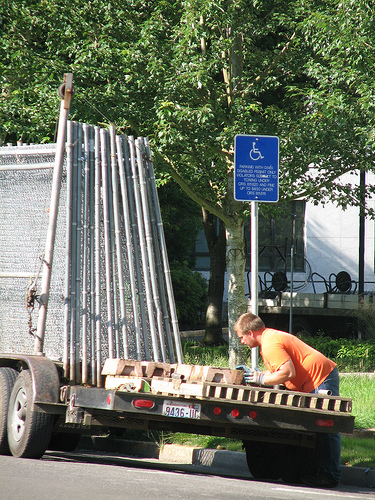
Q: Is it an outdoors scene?
A: Yes, it is outdoors.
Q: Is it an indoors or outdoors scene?
A: It is outdoors.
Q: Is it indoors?
A: No, it is outdoors.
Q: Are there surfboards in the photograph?
A: No, there are no surfboards.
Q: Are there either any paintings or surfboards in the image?
A: No, there are no surfboards or paintings.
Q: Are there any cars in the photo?
A: No, there are no cars.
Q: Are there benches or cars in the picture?
A: No, there are no cars or benches.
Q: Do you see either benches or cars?
A: No, there are no cars or benches.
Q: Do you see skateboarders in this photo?
A: No, there are no skateboarders.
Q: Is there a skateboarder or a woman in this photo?
A: No, there are no skateboarders or women.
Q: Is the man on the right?
A: Yes, the man is on the right of the image.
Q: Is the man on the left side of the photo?
A: No, the man is on the right of the image.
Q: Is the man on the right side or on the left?
A: The man is on the right of the image.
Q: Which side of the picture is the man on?
A: The man is on the right of the image.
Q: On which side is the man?
A: The man is on the right of the image.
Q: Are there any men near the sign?
A: Yes, there is a man near the sign.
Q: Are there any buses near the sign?
A: No, there is a man near the sign.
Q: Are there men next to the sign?
A: Yes, there is a man next to the sign.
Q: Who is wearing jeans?
A: The man is wearing jeans.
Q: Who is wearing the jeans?
A: The man is wearing jeans.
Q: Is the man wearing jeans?
A: Yes, the man is wearing jeans.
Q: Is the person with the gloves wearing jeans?
A: Yes, the man is wearing jeans.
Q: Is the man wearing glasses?
A: No, the man is wearing jeans.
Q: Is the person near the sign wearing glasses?
A: No, the man is wearing jeans.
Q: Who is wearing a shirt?
A: The man is wearing a shirt.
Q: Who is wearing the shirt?
A: The man is wearing a shirt.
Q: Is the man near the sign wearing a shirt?
A: Yes, the man is wearing a shirt.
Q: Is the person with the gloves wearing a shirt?
A: Yes, the man is wearing a shirt.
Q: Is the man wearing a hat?
A: No, the man is wearing a shirt.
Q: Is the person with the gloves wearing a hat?
A: No, the man is wearing a shirt.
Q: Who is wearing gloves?
A: The man is wearing gloves.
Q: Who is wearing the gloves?
A: The man is wearing gloves.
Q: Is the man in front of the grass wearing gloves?
A: Yes, the man is wearing gloves.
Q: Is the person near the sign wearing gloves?
A: Yes, the man is wearing gloves.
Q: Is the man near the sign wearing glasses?
A: No, the man is wearing gloves.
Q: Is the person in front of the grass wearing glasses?
A: No, the man is wearing gloves.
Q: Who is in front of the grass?
A: The man is in front of the grass.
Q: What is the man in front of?
A: The man is in front of the grass.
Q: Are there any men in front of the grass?
A: Yes, there is a man in front of the grass.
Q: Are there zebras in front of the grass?
A: No, there is a man in front of the grass.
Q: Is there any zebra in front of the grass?
A: No, there is a man in front of the grass.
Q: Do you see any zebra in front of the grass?
A: No, there is a man in front of the grass.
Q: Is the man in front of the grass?
A: Yes, the man is in front of the grass.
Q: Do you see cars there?
A: No, there are no cars.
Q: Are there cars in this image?
A: No, there are no cars.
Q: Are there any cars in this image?
A: No, there are no cars.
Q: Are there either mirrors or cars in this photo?
A: No, there are no cars or mirrors.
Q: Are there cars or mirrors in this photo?
A: No, there are no cars or mirrors.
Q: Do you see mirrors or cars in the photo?
A: No, there are no cars or mirrors.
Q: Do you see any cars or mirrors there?
A: No, there are no cars or mirrors.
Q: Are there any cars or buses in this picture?
A: No, there are no cars or buses.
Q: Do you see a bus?
A: No, there are no buses.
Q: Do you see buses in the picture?
A: No, there are no buses.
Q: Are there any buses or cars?
A: No, there are no buses or cars.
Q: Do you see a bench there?
A: No, there are no benches.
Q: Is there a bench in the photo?
A: No, there are no benches.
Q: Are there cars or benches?
A: No, there are no benches or cars.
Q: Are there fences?
A: Yes, there is a fence.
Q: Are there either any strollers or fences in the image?
A: Yes, there is a fence.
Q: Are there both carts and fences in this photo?
A: No, there is a fence but no carts.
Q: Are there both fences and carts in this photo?
A: No, there is a fence but no carts.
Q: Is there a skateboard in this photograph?
A: No, there are no skateboards.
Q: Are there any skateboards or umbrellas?
A: No, there are no skateboards or umbrellas.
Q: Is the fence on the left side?
A: Yes, the fence is on the left of the image.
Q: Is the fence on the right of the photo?
A: No, the fence is on the left of the image.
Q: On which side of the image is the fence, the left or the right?
A: The fence is on the left of the image.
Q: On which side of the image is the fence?
A: The fence is on the left of the image.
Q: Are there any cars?
A: No, there are no cars.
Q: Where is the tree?
A: The tree is in the yard.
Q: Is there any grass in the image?
A: Yes, there is grass.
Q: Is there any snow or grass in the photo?
A: Yes, there is grass.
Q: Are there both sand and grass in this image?
A: No, there is grass but no sand.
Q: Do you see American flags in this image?
A: No, there are no American flags.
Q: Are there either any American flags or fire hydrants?
A: No, there are no American flags or fire hydrants.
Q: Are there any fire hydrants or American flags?
A: No, there are no American flags or fire hydrants.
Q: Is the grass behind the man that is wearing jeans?
A: Yes, the grass is behind the man.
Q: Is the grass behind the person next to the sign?
A: Yes, the grass is behind the man.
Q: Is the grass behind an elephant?
A: No, the grass is behind the man.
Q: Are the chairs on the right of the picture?
A: Yes, the chairs are on the right of the image.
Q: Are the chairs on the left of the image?
A: No, the chairs are on the right of the image.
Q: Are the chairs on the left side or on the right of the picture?
A: The chairs are on the right of the image.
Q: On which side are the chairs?
A: The chairs are on the right of the image.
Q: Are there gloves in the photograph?
A: Yes, there are gloves.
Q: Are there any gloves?
A: Yes, there are gloves.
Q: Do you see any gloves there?
A: Yes, there are gloves.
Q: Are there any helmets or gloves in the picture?
A: Yes, there are gloves.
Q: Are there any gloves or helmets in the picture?
A: Yes, there are gloves.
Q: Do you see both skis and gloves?
A: No, there are gloves but no skis.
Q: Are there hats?
A: No, there are no hats.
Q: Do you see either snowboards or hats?
A: No, there are no hats or snowboards.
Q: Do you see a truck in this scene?
A: Yes, there is a truck.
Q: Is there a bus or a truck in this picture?
A: Yes, there is a truck.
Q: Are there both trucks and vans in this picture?
A: No, there is a truck but no vans.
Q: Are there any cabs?
A: No, there are no cabs.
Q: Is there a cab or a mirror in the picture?
A: No, there are no taxis or mirrors.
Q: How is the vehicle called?
A: The vehicle is a truck.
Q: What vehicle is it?
A: The vehicle is a truck.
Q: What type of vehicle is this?
A: That is a truck.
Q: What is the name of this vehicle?
A: That is a truck.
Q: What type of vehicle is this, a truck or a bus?
A: That is a truck.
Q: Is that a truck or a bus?
A: That is a truck.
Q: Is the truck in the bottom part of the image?
A: Yes, the truck is in the bottom of the image.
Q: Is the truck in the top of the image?
A: No, the truck is in the bottom of the image.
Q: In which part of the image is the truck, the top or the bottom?
A: The truck is in the bottom of the image.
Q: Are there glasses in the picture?
A: No, there are no glasses.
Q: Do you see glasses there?
A: No, there are no glasses.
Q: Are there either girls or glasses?
A: No, there are no glasses or girls.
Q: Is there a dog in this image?
A: No, there are no dogs.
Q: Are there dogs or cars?
A: No, there are no dogs or cars.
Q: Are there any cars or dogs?
A: No, there are no dogs or cars.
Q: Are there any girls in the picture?
A: No, there are no girls.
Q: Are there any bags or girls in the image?
A: No, there are no girls or bags.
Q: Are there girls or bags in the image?
A: No, there are no girls or bags.